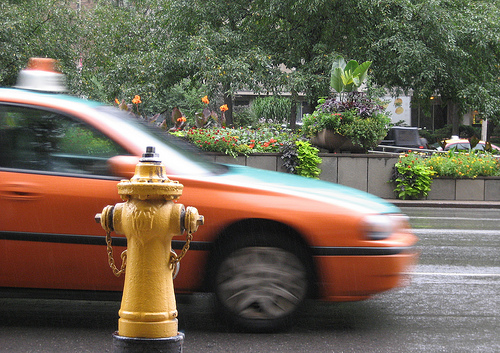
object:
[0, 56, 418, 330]
taxi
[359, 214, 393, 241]
streetlight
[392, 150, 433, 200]
plant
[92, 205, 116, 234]
faucet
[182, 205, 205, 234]
faucet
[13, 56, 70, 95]
sign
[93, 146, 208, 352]
fire hydrant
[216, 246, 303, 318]
grill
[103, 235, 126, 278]
chain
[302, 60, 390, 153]
plant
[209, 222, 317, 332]
wheel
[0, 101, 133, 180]
window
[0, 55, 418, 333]
car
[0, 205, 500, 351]
street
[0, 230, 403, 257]
bumper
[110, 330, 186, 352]
base